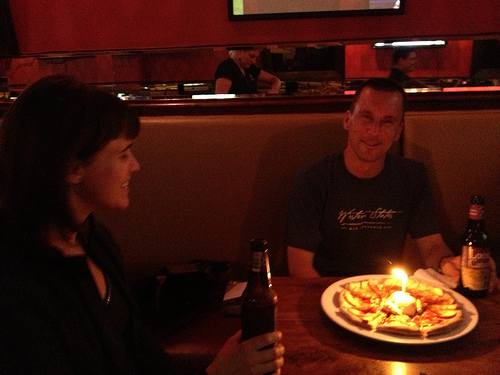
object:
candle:
[402, 280, 405, 298]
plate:
[320, 273, 480, 345]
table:
[266, 263, 497, 374]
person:
[285, 77, 444, 295]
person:
[0, 73, 146, 374]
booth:
[89, 91, 499, 373]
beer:
[459, 193, 490, 298]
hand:
[439, 252, 461, 285]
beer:
[239, 236, 279, 374]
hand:
[205, 328, 285, 374]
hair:
[1, 72, 141, 264]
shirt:
[0, 215, 141, 374]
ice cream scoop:
[387, 290, 416, 314]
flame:
[390, 266, 410, 284]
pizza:
[339, 278, 463, 336]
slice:
[377, 320, 395, 336]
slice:
[419, 309, 431, 316]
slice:
[373, 318, 391, 330]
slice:
[365, 289, 380, 302]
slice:
[343, 277, 365, 293]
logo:
[336, 207, 395, 220]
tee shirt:
[285, 149, 442, 276]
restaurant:
[0, 1, 499, 374]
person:
[214, 47, 282, 96]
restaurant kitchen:
[0, 30, 499, 87]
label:
[461, 245, 490, 291]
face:
[96, 142, 134, 211]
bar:
[1, 90, 500, 120]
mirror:
[226, 0, 395, 15]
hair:
[349, 76, 405, 124]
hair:
[228, 50, 241, 55]